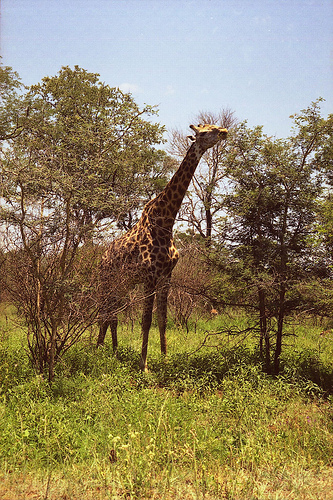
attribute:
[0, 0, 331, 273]
sky — blue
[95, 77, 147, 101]
clouds — white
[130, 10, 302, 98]
sky — blue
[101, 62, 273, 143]
clouds — white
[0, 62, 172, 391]
tree — dead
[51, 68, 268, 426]
giraffe — long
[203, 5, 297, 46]
clouds — white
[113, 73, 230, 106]
clouds — white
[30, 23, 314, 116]
sky — blue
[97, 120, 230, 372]
giraffe — tall, brown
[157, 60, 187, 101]
clouds — white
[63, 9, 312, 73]
sky — blue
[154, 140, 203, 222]
neck — white